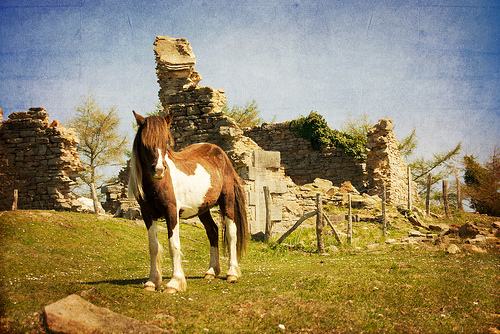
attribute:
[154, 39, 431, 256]
dwelling — small, cottage type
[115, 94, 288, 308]
horse — brown, white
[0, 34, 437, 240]
house — stone, ruined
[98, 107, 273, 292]
horse — white, brown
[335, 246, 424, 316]
plant — green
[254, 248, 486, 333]
grass — short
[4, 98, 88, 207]
rockwall — rustic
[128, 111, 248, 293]
pony — brown and white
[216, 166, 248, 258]
tail — brown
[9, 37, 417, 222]
stone house — ruined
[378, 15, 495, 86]
sky — blue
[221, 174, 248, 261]
tail — long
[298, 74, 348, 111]
sky — clear, blue and white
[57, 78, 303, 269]
animal — farm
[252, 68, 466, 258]
remains — architectural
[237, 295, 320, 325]
grass — green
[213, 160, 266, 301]
tail — brown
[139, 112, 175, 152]
mane — long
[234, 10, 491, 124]
sky — clear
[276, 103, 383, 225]
tree — young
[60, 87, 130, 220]
tree — small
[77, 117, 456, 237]
wall — rock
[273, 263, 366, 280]
leaves — sparse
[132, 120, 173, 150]
hair — shaggy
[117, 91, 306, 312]
horse — young